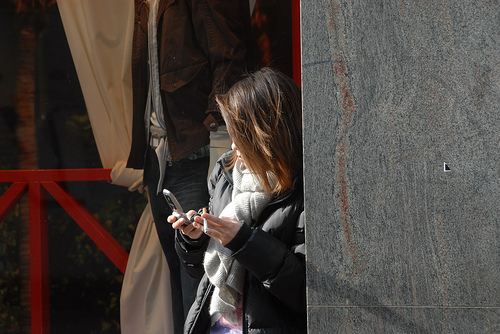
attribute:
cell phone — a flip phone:
[163, 188, 193, 224]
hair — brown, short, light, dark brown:
[214, 67, 301, 198]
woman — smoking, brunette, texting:
[168, 66, 307, 333]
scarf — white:
[203, 158, 279, 316]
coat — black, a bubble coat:
[175, 151, 307, 333]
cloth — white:
[56, 0, 175, 333]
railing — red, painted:
[0, 167, 131, 332]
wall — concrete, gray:
[301, 0, 500, 333]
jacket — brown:
[124, 2, 247, 171]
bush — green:
[57, 192, 151, 332]